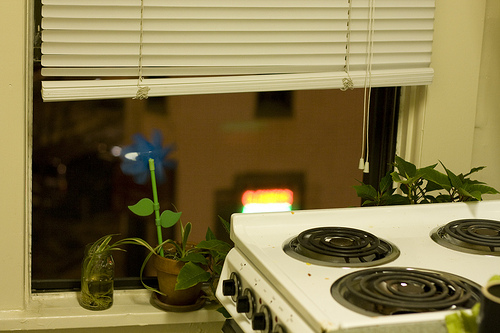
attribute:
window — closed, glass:
[31, 1, 401, 296]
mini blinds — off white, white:
[41, 0, 436, 104]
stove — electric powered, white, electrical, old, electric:
[214, 200, 499, 331]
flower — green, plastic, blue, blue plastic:
[121, 130, 183, 259]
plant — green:
[354, 152, 500, 207]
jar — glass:
[79, 245, 115, 312]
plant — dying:
[78, 232, 157, 307]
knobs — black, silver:
[222, 272, 286, 333]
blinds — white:
[40, 0, 438, 105]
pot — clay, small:
[151, 243, 213, 313]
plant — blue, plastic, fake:
[120, 128, 184, 258]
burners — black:
[282, 219, 498, 318]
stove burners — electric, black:
[283, 219, 498, 318]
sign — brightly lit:
[240, 187, 293, 214]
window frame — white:
[1, 0, 429, 332]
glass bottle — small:
[78, 243, 115, 310]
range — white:
[214, 200, 500, 332]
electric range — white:
[215, 200, 500, 332]